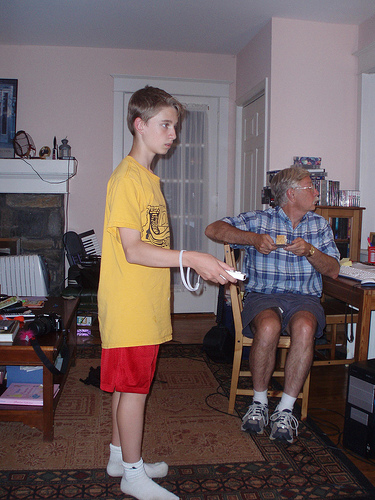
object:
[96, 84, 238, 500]
boy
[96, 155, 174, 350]
shirt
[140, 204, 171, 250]
design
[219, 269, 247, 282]
wii remote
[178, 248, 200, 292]
strap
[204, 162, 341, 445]
man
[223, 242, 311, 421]
chair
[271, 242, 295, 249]
dish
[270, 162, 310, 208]
hair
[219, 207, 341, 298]
shirt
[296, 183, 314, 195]
glasses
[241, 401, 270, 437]
shoes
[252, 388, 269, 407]
socks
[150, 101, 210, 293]
curtain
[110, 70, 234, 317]
door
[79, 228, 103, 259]
keyboard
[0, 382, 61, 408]
book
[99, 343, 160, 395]
shorts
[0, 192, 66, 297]
fireplace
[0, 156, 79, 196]
mantel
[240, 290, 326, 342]
shorts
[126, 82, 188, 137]
hair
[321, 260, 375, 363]
table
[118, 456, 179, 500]
socks